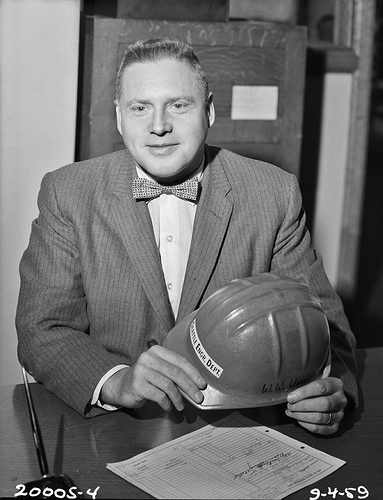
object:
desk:
[0, 344, 382, 499]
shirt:
[131, 154, 205, 324]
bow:
[132, 177, 199, 202]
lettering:
[233, 450, 292, 479]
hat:
[162, 271, 332, 410]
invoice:
[106, 409, 348, 499]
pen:
[18, 363, 51, 480]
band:
[326, 412, 333, 427]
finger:
[286, 409, 345, 424]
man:
[14, 36, 359, 436]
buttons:
[165, 232, 173, 242]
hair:
[114, 37, 211, 100]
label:
[229, 84, 279, 122]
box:
[78, 14, 308, 194]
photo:
[0, 1, 382, 499]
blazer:
[15, 143, 361, 420]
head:
[113, 39, 217, 179]